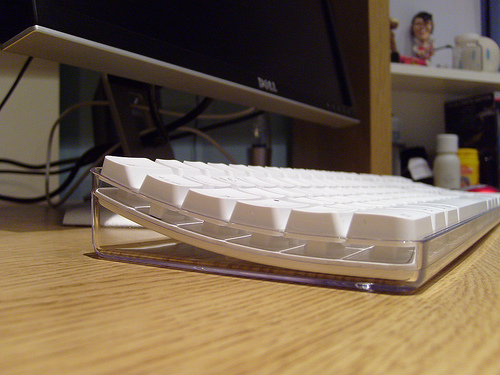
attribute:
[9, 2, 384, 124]
computer — Dell , monitor 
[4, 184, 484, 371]
table — wooden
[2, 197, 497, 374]
table — wooden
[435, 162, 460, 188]
label — white 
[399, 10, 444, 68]
head — Elvis , bobble 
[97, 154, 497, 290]
computer — desktop 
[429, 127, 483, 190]
containers — white 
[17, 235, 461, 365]
table — brown 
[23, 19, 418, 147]
monitor — off 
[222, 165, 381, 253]
keyboard — see through, bottom 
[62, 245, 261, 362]
tabletop — light , wood grain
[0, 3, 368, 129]
monitor — black , grey 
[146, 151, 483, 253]
keys — white 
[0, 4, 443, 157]
screen — off 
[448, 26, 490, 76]
bottle — clear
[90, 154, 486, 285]
keyboard — white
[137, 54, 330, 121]
frame — silver 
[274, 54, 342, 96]
screen — blank 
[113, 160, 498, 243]
board — key 